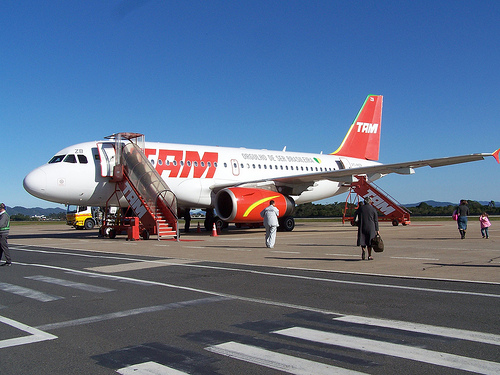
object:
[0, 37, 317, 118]
cloud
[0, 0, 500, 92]
sky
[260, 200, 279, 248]
man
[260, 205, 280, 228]
jacket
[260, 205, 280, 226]
track suit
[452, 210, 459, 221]
bag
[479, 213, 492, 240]
girl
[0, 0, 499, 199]
blue sky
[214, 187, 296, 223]
propellor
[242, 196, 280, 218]
stripe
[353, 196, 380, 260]
man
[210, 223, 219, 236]
cones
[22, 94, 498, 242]
airplane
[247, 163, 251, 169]
windows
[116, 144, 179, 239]
orange stairs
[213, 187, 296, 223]
booster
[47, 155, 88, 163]
cockpit windows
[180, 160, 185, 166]
windows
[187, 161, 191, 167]
windows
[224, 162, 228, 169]
windows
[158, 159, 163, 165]
windows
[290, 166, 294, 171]
windows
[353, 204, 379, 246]
coat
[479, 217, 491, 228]
coat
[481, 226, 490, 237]
jeans